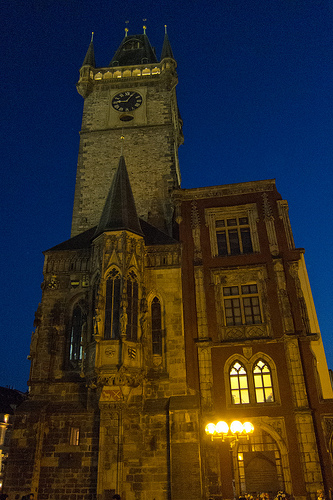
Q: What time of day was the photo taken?
A: Nighttime.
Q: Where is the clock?
A: On the tower.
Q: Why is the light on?
A: It is dark.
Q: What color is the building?
A: Brown.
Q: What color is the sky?
A: Blue.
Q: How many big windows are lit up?
A: Two.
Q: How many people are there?
A: No people.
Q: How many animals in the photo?
A: None.